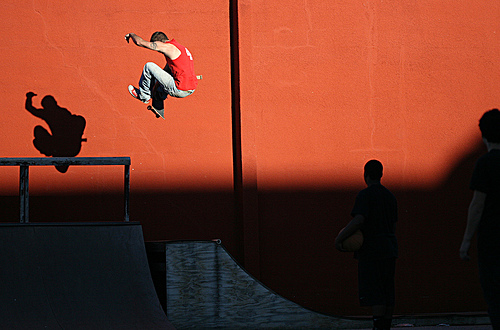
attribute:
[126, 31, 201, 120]
skateboarder — skateboarding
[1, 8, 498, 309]
wall — orange, red, red orange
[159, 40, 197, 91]
shirt — red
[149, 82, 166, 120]
skateboard — black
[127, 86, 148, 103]
sneaker — red, white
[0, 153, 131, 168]
bars — faded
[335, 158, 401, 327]
spectator — standing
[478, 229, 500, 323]
jeans — blue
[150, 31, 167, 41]
hair — brown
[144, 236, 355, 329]
half pipe — wooden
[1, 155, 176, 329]
ramp — metal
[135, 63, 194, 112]
jeans — khaki